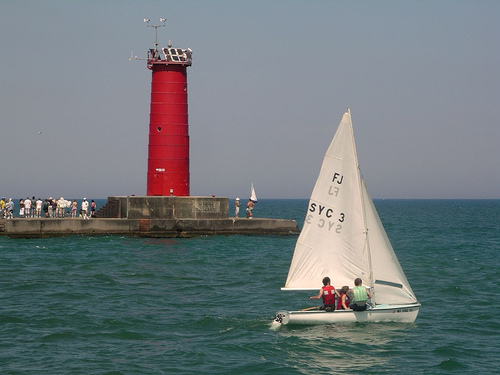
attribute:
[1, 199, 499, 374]
water — blue, wavy, seawater, sea, large, aqua colored, moving, rippling, wavey, ocean, from sea, from ocean, not calm, ocean water, rippled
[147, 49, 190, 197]
light house — here, red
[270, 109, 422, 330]
sailboat — small, painted white, white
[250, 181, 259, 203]
sailboat — painted white, in distance, white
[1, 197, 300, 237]
pier — grey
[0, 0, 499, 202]
sky — blue, hazy